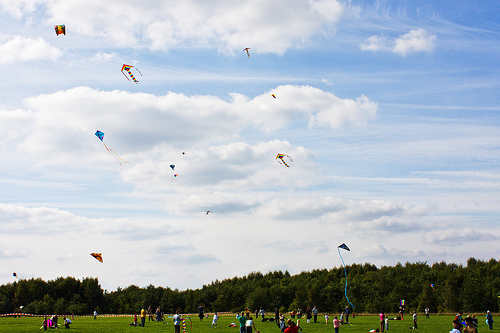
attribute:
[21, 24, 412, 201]
sky — cloudy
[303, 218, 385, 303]
kites — flying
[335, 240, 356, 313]
kite — blue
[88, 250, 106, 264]
kite — red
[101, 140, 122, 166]
tail — long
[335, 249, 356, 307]
tail — long, green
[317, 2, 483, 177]
sky — blue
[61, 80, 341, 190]
clouds — white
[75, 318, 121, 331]
grass — green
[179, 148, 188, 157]
kite — barely visible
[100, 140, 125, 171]
tail — long , red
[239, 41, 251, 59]
kite — flying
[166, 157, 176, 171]
kite — flying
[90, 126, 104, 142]
kite — flying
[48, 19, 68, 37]
kite — flying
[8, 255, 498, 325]
forrest — distant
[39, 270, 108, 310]
trees — distant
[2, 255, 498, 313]
trees — dark green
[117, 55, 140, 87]
kite — arrow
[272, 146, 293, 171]
kite — flying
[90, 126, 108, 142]
kite — blue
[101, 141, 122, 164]
tail — orange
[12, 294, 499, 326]
people — grouped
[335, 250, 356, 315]
tail — long, blue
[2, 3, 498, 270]
clouds — white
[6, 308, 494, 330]
grass — bright green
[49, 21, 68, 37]
kite — flying , high